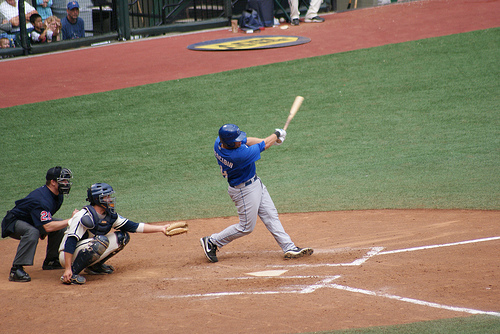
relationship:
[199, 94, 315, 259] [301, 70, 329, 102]
baseball player batting baseball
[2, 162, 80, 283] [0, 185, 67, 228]
man wearing black shirt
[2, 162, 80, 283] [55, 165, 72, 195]
man has on guard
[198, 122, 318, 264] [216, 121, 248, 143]
baseball player has on helmet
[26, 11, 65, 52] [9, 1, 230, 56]
kid in stands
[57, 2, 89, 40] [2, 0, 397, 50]
man sitting in stand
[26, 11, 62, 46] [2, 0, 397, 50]
kid sitting in stand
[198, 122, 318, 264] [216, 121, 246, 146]
baseball player wearing helmet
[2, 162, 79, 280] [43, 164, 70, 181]
man wearing helmet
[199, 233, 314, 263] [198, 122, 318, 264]
feet of a baseball player